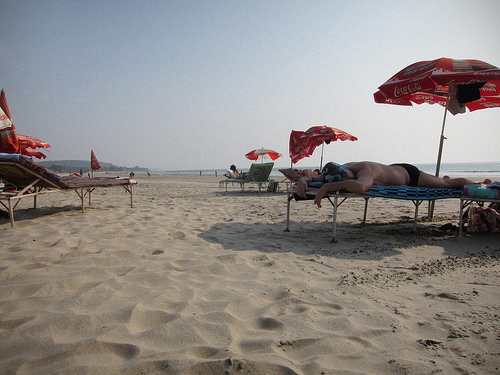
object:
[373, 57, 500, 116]
umbrella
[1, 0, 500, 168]
sky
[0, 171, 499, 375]
beach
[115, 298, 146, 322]
bunch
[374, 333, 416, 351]
sand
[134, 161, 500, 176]
ocean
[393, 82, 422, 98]
logo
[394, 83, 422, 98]
coca-cola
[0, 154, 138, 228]
chair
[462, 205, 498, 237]
bag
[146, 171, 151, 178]
beach goer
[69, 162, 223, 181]
distance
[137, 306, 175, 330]
print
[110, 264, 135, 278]
print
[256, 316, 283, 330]
print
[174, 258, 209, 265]
print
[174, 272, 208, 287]
print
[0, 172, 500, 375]
ground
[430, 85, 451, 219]
pole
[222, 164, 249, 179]
recliner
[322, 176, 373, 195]
arm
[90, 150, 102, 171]
umbrella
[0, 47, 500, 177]
background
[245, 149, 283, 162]
umbrella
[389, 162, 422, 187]
bathing suit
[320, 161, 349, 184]
hat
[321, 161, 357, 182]
head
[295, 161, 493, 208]
man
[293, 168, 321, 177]
woman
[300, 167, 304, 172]
cell phone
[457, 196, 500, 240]
table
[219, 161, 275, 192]
beach chair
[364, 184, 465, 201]
towel